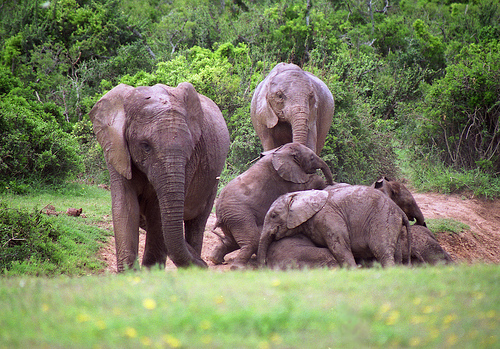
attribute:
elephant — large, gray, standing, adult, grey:
[85, 75, 236, 268]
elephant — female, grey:
[236, 46, 336, 199]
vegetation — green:
[16, 43, 81, 208]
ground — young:
[419, 154, 456, 172]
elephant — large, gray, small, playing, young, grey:
[256, 183, 412, 267]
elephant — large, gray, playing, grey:
[263, 175, 428, 268]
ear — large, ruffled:
[88, 80, 133, 180]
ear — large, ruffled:
[176, 79, 206, 133]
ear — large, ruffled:
[256, 73, 281, 131]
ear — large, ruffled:
[270, 148, 312, 184]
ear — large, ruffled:
[285, 188, 330, 229]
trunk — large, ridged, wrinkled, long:
[146, 156, 206, 268]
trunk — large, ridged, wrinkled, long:
[287, 111, 310, 147]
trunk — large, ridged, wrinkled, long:
[318, 158, 335, 186]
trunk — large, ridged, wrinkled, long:
[257, 226, 277, 265]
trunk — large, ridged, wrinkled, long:
[408, 190, 427, 228]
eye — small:
[138, 142, 151, 151]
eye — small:
[275, 91, 285, 100]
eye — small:
[308, 153, 315, 161]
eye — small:
[270, 211, 277, 220]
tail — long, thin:
[209, 220, 229, 246]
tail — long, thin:
[403, 212, 415, 265]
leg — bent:
[223, 205, 259, 265]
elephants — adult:
[87, 79, 229, 269]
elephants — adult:
[250, 61, 334, 166]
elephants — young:
[205, 142, 333, 271]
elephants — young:
[369, 173, 425, 228]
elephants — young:
[387, 218, 456, 268]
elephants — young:
[255, 180, 415, 270]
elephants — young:
[263, 232, 340, 271]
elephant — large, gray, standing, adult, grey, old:
[250, 62, 336, 152]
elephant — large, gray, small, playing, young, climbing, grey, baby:
[211, 140, 333, 271]